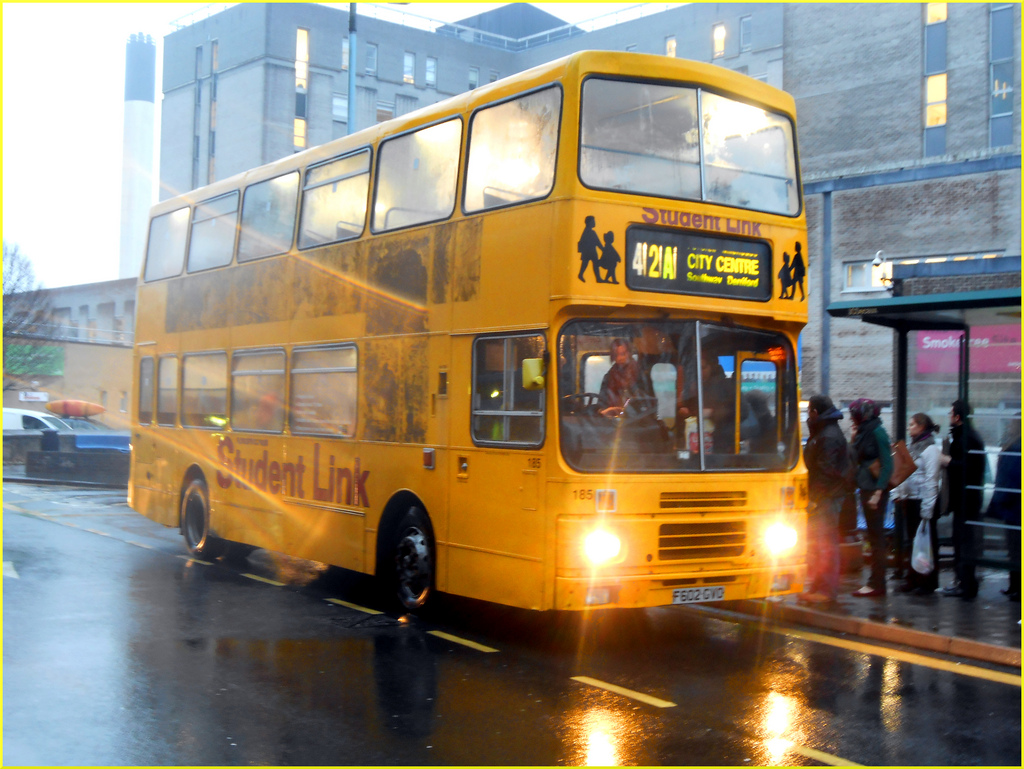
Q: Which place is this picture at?
A: It is at the road.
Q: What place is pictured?
A: It is a road.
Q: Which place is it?
A: It is a road.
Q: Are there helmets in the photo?
A: No, there are no helmets.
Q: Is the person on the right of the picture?
A: Yes, the person is on the right of the image.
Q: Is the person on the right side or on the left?
A: The person is on the right of the image.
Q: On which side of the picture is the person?
A: The person is on the right of the image.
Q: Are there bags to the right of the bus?
A: No, there is a person to the right of the bus.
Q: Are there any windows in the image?
A: Yes, there is a window.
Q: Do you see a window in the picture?
A: Yes, there is a window.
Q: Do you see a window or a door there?
A: Yes, there is a window.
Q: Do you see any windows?
A: Yes, there is a window.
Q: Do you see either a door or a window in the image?
A: Yes, there is a window.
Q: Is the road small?
A: Yes, the road is small.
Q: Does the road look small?
A: Yes, the road is small.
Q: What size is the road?
A: The road is small.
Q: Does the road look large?
A: No, the road is small.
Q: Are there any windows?
A: Yes, there is a window.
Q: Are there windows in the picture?
A: Yes, there is a window.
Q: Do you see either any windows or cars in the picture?
A: Yes, there is a window.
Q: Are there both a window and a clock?
A: No, there is a window but no clocks.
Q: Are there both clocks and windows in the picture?
A: No, there is a window but no clocks.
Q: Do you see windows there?
A: Yes, there is a window.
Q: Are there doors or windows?
A: Yes, there is a window.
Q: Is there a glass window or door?
A: Yes, there is a glass window.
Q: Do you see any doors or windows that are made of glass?
A: Yes, the window is made of glass.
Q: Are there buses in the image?
A: Yes, there is a bus.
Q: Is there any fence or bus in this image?
A: Yes, there is a bus.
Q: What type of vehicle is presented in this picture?
A: The vehicle is a bus.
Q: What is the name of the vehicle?
A: The vehicle is a bus.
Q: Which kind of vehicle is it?
A: The vehicle is a bus.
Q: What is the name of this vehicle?
A: That is a bus.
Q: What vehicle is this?
A: That is a bus.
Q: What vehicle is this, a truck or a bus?
A: That is a bus.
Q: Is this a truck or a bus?
A: This is a bus.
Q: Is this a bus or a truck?
A: This is a bus.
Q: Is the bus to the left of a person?
A: Yes, the bus is to the left of a person.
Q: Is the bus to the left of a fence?
A: No, the bus is to the left of a person.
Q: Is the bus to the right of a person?
A: No, the bus is to the left of a person.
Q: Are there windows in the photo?
A: Yes, there is a window.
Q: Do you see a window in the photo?
A: Yes, there is a window.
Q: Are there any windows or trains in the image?
A: Yes, there is a window.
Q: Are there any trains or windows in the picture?
A: Yes, there is a window.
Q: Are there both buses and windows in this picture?
A: Yes, there are both a window and a bus.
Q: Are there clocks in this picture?
A: No, there are no clocks.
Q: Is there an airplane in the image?
A: No, there are no airplanes.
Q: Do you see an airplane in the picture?
A: No, there are no airplanes.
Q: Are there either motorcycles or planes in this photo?
A: No, there are no planes or motorcycles.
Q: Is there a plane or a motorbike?
A: No, there are no airplanes or motorcycles.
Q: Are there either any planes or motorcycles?
A: No, there are no planes or motorcycles.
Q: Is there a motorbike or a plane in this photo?
A: No, there are no airplanes or motorcycles.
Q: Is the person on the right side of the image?
A: Yes, the person is on the right of the image.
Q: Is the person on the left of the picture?
A: No, the person is on the right of the image.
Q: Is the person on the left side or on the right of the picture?
A: The person is on the right of the image.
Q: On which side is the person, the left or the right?
A: The person is on the right of the image.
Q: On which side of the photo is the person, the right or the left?
A: The person is on the right of the image.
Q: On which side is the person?
A: The person is on the right of the image.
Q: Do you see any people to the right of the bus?
A: Yes, there is a person to the right of the bus.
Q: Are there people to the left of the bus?
A: No, the person is to the right of the bus.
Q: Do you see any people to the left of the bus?
A: No, the person is to the right of the bus.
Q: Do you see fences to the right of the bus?
A: No, there is a person to the right of the bus.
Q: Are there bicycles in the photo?
A: No, there are no bicycles.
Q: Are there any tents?
A: No, there are no tents.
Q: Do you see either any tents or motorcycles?
A: No, there are no tents or motorcycles.